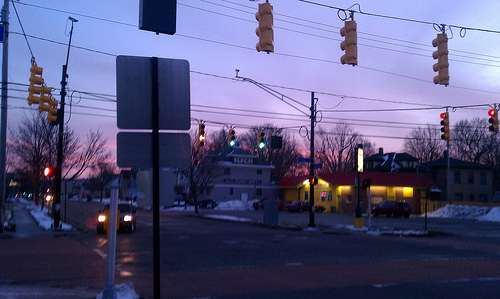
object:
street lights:
[338, 20, 360, 68]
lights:
[229, 140, 237, 147]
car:
[95, 202, 140, 236]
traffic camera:
[63, 15, 79, 66]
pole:
[53, 64, 70, 230]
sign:
[320, 191, 326, 202]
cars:
[284, 200, 310, 213]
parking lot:
[210, 192, 477, 235]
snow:
[419, 202, 500, 222]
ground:
[0, 199, 500, 299]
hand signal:
[42, 167, 56, 177]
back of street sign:
[115, 53, 192, 130]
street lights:
[439, 111, 447, 118]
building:
[276, 170, 438, 215]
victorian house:
[398, 149, 497, 203]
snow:
[15, 196, 78, 232]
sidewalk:
[7, 196, 88, 235]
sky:
[0, 0, 497, 183]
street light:
[253, 2, 275, 55]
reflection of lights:
[94, 231, 138, 279]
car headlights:
[97, 214, 106, 222]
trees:
[4, 105, 87, 207]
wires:
[18, 2, 500, 94]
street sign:
[429, 186, 442, 193]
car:
[370, 199, 414, 219]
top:
[277, 170, 435, 189]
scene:
[1, 1, 500, 295]